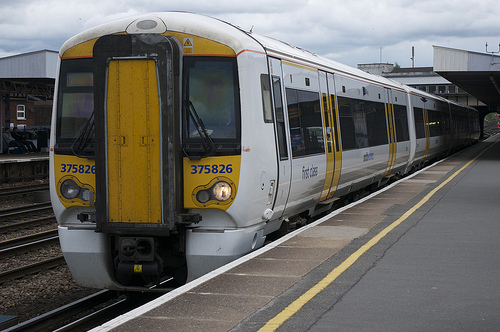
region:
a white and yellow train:
[51, 10, 488, 284]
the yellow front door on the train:
[105, 54, 165, 220]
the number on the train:
[191, 164, 231, 174]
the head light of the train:
[213, 180, 231, 200]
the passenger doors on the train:
[318, 71, 343, 196]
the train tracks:
[0, 179, 56, 330]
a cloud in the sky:
[271, 0, 499, 43]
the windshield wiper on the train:
[178, 100, 215, 153]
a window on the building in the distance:
[17, 103, 25, 117]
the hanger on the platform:
[431, 43, 498, 104]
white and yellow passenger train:
[62, 37, 417, 185]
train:
[78, 9, 414, 198]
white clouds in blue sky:
[5, 14, 53, 56]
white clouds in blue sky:
[284, 12, 319, 38]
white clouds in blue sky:
[336, 11, 372, 46]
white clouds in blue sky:
[366, 9, 426, 41]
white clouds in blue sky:
[413, 18, 493, 33]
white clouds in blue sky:
[315, 18, 349, 53]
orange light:
[208, 176, 254, 208]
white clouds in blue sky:
[48, 14, 96, 25]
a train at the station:
[42, 2, 487, 302]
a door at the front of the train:
[100, 54, 165, 227]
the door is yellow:
[105, 52, 164, 226]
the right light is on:
[212, 180, 233, 202]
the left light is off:
[57, 174, 82, 201]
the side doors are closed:
[317, 92, 342, 202]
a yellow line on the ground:
[227, 137, 497, 331]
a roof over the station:
[428, 38, 498, 116]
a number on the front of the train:
[186, 159, 234, 178]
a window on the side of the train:
[283, 87, 328, 164]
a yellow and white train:
[52, 13, 491, 253]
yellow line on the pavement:
[259, 145, 474, 330]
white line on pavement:
[118, 148, 450, 330]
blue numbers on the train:
[183, 158, 245, 179]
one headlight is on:
[208, 175, 237, 207]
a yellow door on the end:
[88, 38, 190, 273]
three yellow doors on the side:
[306, 72, 471, 186]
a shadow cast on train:
[416, 46, 499, 173]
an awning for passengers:
[428, 40, 495, 145]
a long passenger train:
[44, 4, 496, 319]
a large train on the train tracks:
[44, 20, 420, 298]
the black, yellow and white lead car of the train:
[43, 15, 258, 238]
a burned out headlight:
[53, 170, 92, 207]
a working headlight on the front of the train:
[188, 173, 238, 214]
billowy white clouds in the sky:
[262, 2, 498, 54]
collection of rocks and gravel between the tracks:
[13, 272, 73, 313]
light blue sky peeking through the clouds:
[388, 46, 408, 60]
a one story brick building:
[3, 76, 48, 153]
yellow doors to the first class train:
[319, 83, 342, 205]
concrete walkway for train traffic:
[342, 200, 499, 330]